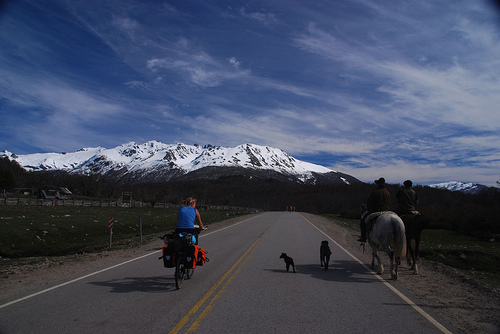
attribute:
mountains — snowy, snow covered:
[183, 144, 258, 176]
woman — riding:
[177, 193, 207, 236]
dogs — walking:
[265, 230, 334, 279]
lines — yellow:
[167, 297, 217, 325]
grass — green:
[96, 211, 135, 231]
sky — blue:
[205, 25, 262, 61]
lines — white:
[70, 273, 94, 288]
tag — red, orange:
[186, 242, 215, 269]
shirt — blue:
[177, 208, 202, 230]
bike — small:
[166, 229, 216, 285]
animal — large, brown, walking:
[401, 214, 429, 253]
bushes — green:
[450, 206, 477, 236]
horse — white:
[356, 204, 406, 259]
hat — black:
[374, 177, 388, 185]